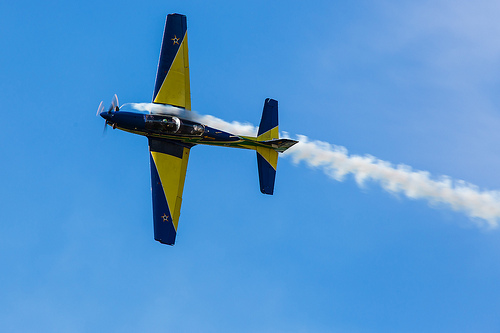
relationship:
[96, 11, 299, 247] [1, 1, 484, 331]
airplane in sky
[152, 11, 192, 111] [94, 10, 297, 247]
wing attached to plane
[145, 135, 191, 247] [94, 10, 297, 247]
wing attached to plane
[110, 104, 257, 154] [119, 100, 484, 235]
engine producing smoke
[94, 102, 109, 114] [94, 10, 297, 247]
helix lifting plane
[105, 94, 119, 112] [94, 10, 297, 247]
helix lifting plane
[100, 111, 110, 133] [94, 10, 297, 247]
helix lifting plane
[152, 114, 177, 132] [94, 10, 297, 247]
seat built into plane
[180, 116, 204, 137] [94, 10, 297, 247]
seat built into plane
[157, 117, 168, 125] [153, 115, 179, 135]
pilot sitting in seat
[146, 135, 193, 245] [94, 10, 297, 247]
left wing attached to plane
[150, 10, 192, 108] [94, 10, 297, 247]
right wing attached to plane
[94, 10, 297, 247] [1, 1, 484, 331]
plane flying in sky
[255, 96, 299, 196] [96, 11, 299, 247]
tail attached to airplane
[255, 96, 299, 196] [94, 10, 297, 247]
tail attached to plane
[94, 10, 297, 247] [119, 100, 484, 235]
plane emitting smoke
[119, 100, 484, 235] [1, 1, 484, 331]
smoke emitted in sky